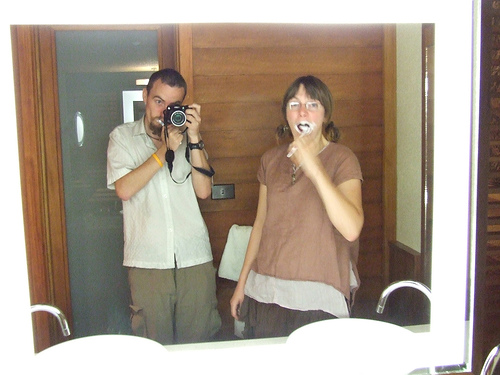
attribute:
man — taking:
[95, 69, 227, 309]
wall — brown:
[205, 40, 415, 320]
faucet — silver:
[366, 260, 487, 374]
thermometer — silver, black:
[207, 177, 241, 206]